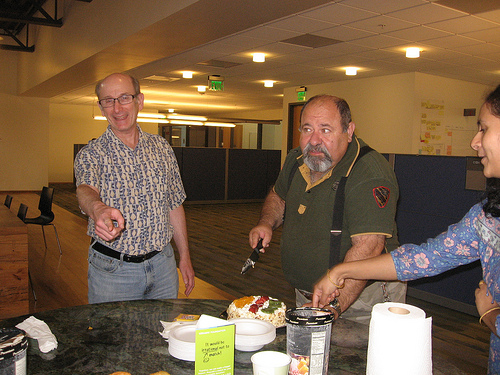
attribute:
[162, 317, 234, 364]
plates — paper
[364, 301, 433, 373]
bowls — paper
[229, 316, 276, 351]
bowls — paper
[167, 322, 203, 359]
bowls — paper